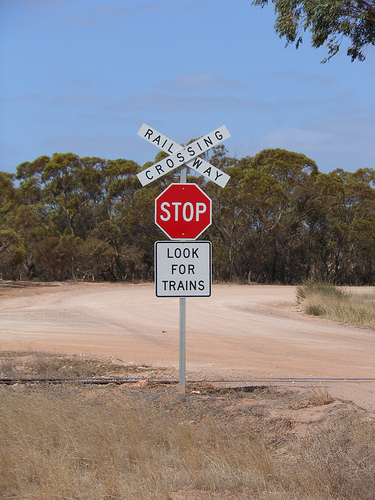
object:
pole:
[179, 166, 185, 395]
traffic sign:
[135, 120, 232, 192]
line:
[0, 375, 374, 385]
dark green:
[235, 158, 263, 195]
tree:
[0, 138, 374, 287]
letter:
[159, 201, 171, 224]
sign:
[134, 122, 234, 188]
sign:
[152, 240, 213, 297]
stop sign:
[154, 182, 213, 242]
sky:
[0, 0, 374, 210]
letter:
[182, 199, 193, 223]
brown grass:
[0, 348, 374, 498]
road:
[0, 282, 374, 411]